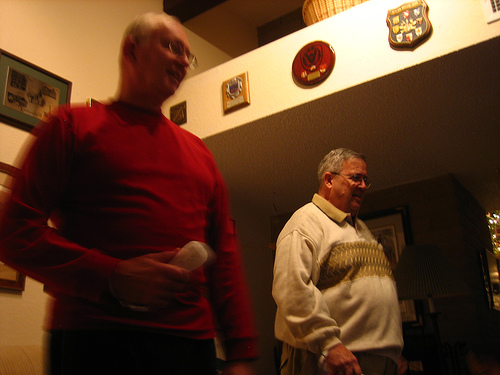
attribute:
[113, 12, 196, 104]
head — blurry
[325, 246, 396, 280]
stripe — green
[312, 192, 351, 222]
collar — yellow